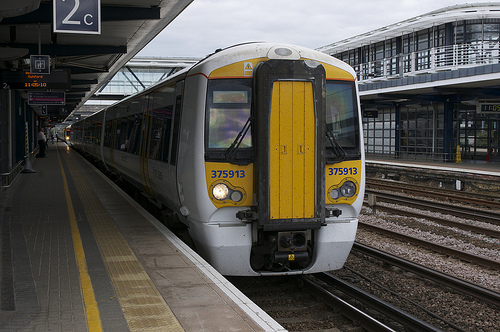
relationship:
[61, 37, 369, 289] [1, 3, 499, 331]
train in station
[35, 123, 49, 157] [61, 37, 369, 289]
man waiting for train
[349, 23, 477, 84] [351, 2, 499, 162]
windows are on building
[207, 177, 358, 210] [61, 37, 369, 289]
headlights on train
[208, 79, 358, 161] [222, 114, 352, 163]
windshields with wipes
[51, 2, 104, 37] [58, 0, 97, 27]
signs with lettering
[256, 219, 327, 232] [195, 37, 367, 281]
slats on front of train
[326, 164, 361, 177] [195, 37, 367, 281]
number 375913 on front train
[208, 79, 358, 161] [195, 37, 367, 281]
windows on front train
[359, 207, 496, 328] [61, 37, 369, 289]
tracks beside train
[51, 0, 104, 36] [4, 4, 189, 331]
signs along train depot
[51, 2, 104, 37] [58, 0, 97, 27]
sign says 2c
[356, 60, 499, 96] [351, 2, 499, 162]
balcony on building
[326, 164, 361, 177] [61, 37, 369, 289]
number 375913 on train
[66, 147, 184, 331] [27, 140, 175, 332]
stripe on walkway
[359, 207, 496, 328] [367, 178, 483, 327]
gravel between tracks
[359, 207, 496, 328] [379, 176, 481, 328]
gravel between tracks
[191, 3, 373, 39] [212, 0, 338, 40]
clouds in sky